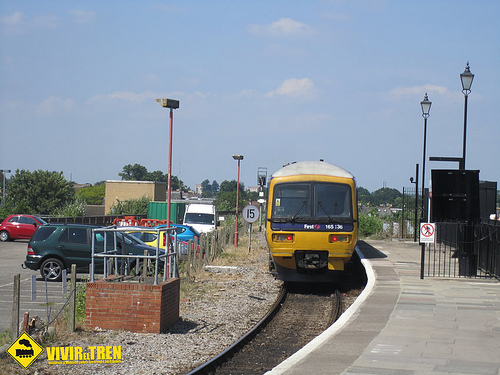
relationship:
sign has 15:
[240, 202, 261, 226] [247, 208, 254, 218]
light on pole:
[419, 92, 434, 121] [418, 117, 429, 283]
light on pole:
[453, 60, 476, 98] [458, 95, 469, 173]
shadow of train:
[355, 235, 386, 263] [262, 157, 361, 282]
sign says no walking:
[416, 221, 436, 245] [424, 226, 431, 236]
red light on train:
[284, 233, 292, 241] [262, 157, 361, 282]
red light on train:
[330, 235, 339, 245] [262, 157, 361, 282]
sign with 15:
[240, 202, 261, 226] [247, 208, 254, 218]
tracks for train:
[186, 280, 344, 375] [262, 157, 361, 282]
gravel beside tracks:
[0, 266, 280, 374] [186, 280, 344, 375]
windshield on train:
[266, 179, 355, 226] [262, 157, 361, 282]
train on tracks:
[262, 157, 361, 282] [186, 280, 344, 375]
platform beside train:
[263, 237, 499, 374] [262, 157, 361, 282]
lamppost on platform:
[415, 85, 430, 278] [263, 237, 499, 374]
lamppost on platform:
[451, 61, 476, 174] [263, 237, 499, 374]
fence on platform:
[415, 221, 499, 280] [263, 237, 499, 374]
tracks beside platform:
[186, 280, 344, 375] [263, 237, 499, 374]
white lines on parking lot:
[2, 272, 75, 317] [0, 239, 109, 346]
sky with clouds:
[1, 1, 499, 193] [268, 10, 453, 112]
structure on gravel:
[85, 274, 180, 333] [0, 266, 280, 374]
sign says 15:
[240, 202, 261, 226] [247, 208, 254, 218]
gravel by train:
[0, 266, 280, 374] [262, 157, 361, 282]